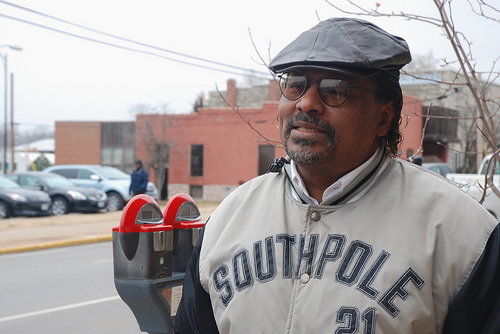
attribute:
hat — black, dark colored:
[267, 16, 413, 73]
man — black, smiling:
[269, 68, 400, 181]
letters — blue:
[203, 228, 429, 319]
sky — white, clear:
[1, 4, 498, 110]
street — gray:
[2, 237, 151, 333]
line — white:
[0, 286, 132, 332]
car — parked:
[44, 162, 163, 209]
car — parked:
[16, 168, 113, 211]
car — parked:
[1, 173, 51, 217]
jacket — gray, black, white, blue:
[196, 164, 499, 326]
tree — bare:
[343, 2, 498, 196]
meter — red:
[110, 190, 214, 234]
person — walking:
[121, 156, 156, 203]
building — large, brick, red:
[46, 101, 425, 192]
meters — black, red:
[112, 187, 206, 332]